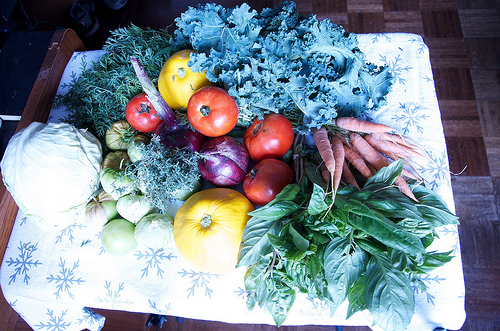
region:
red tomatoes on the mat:
[109, 87, 295, 165]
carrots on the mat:
[275, 116, 445, 201]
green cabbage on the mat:
[1, 113, 118, 225]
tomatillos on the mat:
[67, 119, 175, 252]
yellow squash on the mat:
[147, 49, 272, 304]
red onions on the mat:
[158, 110, 269, 197]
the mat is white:
[8, 22, 477, 329]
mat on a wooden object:
[0, 5, 109, 325]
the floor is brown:
[112, 2, 499, 329]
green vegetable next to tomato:
[51, 22, 163, 133]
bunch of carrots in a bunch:
[313, 105, 400, 168]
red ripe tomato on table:
[246, 164, 276, 202]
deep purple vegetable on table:
[199, 137, 252, 192]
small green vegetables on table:
[102, 227, 133, 262]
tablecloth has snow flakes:
[17, 250, 49, 283]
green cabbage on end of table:
[7, 118, 92, 220]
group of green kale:
[264, 62, 305, 109]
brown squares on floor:
[443, 72, 479, 147]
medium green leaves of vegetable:
[358, 194, 391, 274]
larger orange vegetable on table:
[166, 70, 203, 109]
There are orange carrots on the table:
[329, 103, 386, 190]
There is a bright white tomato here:
[195, 81, 237, 136]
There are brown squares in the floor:
[456, 76, 481, 129]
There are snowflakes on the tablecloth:
[58, 253, 76, 285]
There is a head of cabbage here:
[26, 122, 69, 219]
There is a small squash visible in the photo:
[181, 180, 228, 223]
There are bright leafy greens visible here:
[245, 31, 300, 104]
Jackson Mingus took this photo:
[68, 43, 385, 326]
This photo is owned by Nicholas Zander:
[88, 46, 335, 199]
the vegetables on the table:
[0, 2, 459, 329]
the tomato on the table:
[125, 94, 160, 130]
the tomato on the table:
[186, 85, 237, 133]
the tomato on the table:
[242, 112, 294, 159]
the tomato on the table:
[242, 157, 296, 204]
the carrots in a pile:
[310, 115, 427, 205]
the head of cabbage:
[0, 121, 102, 221]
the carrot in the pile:
[312, 125, 334, 174]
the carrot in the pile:
[335, 114, 394, 134]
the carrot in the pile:
[348, 132, 418, 204]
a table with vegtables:
[0, 36, 445, 302]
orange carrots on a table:
[312, 120, 414, 185]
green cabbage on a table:
[4, 117, 104, 227]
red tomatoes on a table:
[248, 126, 293, 210]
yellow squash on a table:
[155, 49, 206, 120]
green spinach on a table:
[247, 188, 419, 310]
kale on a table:
[183, 8, 396, 128]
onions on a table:
[98, 176, 156, 260]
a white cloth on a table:
[9, 257, 194, 324]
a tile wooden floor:
[446, 11, 489, 186]